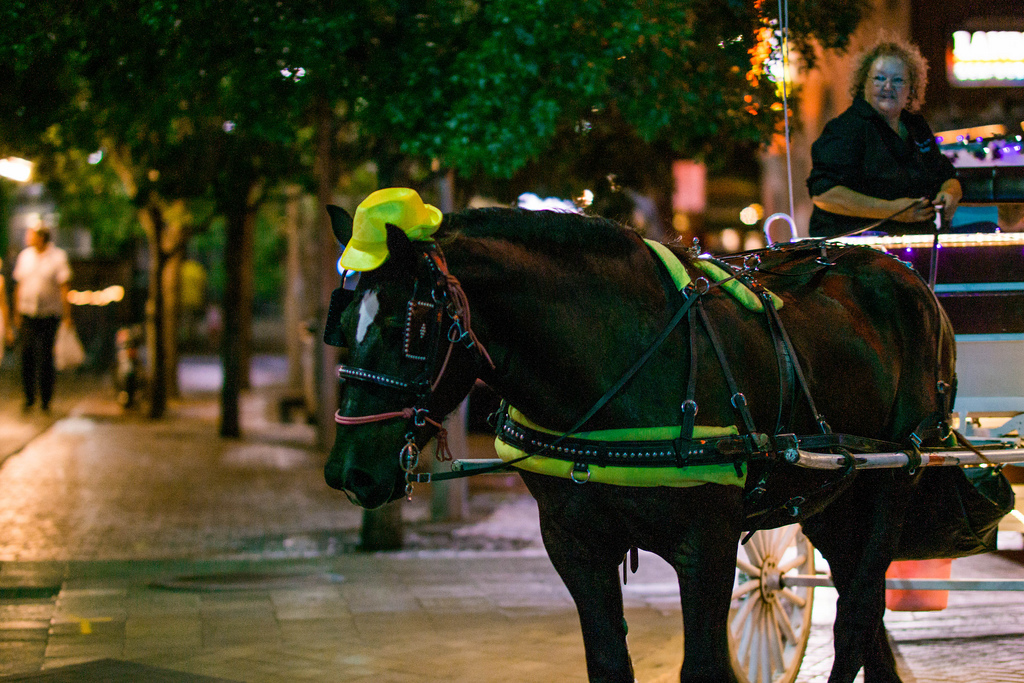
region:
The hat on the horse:
[321, 165, 423, 267]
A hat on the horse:
[333, 155, 439, 274]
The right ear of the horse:
[380, 215, 420, 250]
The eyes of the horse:
[330, 301, 408, 339]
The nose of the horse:
[314, 458, 381, 490]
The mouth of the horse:
[337, 478, 421, 511]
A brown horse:
[245, 133, 948, 665]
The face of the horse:
[274, 221, 471, 494]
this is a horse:
[274, 130, 1001, 659]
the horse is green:
[297, 165, 471, 299]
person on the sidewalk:
[3, 197, 106, 426]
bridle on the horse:
[236, 161, 535, 553]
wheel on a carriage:
[695, 484, 879, 671]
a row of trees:
[19, 14, 842, 526]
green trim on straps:
[616, 216, 814, 365]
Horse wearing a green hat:
[296, 149, 983, 678]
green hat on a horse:
[327, 183, 451, 279]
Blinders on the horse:
[311, 278, 452, 374]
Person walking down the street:
[0, 211, 78, 423]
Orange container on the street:
[882, 556, 956, 615]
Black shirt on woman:
[791, 94, 962, 246]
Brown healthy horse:
[308, 188, 964, 678]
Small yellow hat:
[329, 181, 448, 284]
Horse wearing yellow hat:
[308, 182, 963, 679]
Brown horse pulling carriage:
[313, 179, 1021, 679]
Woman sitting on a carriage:
[725, 23, 1020, 679]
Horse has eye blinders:
[310, 181, 963, 679]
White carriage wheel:
[716, 519, 827, 679]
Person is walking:
[8, 216, 86, 413]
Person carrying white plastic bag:
[8, 216, 88, 417]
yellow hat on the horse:
[321, 186, 462, 285]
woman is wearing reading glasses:
[853, 69, 924, 92]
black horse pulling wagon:
[333, 160, 932, 631]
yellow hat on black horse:
[333, 165, 447, 284]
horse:
[295, 186, 994, 633]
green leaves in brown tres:
[29, 40, 134, 98]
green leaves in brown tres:
[272, 57, 353, 103]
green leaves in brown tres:
[573, 69, 643, 124]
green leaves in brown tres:
[658, 43, 719, 136]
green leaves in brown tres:
[152, 83, 274, 161]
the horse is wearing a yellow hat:
[307, 183, 510, 498]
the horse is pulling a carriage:
[296, 177, 1021, 668]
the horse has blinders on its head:
[315, 281, 440, 368]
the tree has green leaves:
[11, 9, 726, 165]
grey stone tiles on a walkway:
[27, 559, 476, 680]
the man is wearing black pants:
[16, 222, 80, 415]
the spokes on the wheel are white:
[728, 521, 814, 680]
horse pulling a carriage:
[309, 40, 1012, 679]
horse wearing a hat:
[300, 174, 463, 296]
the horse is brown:
[281, 94, 983, 679]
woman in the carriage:
[768, 18, 975, 269]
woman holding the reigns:
[784, 37, 975, 285]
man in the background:
[7, 198, 94, 427]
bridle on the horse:
[287, 195, 504, 472]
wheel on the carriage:
[724, 516, 820, 678]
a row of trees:
[25, 10, 468, 510]